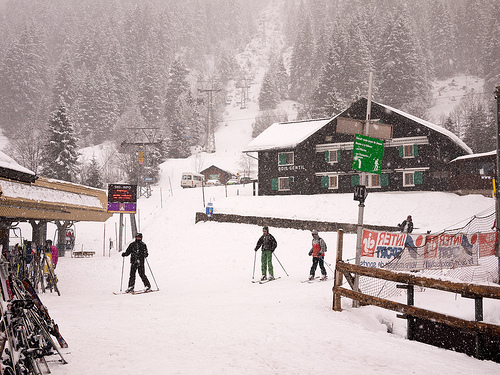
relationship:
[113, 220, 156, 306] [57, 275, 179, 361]
skier going down hill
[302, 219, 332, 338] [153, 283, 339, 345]
skier going down hill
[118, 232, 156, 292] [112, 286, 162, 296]
person on skis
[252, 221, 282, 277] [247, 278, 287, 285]
person on skis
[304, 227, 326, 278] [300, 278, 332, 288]
person on skis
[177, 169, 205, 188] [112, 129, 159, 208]
van beside ski lift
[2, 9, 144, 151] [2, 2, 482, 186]
pine trees on mountain